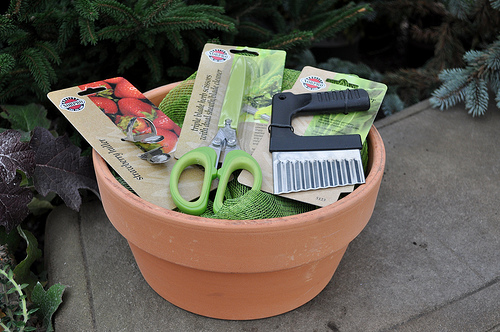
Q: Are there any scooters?
A: No, there are no scooters.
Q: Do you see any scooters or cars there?
A: No, there are no scooters or cars.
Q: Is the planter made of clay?
A: Yes, the planter is made of clay.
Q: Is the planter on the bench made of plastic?
A: No, the planter is made of clay.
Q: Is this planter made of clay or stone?
A: The planter is made of clay.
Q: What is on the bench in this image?
A: The planter is on the bench.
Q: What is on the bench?
A: The planter is on the bench.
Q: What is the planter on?
A: The planter is on the bench.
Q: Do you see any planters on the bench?
A: Yes, there is a planter on the bench.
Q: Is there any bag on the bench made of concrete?
A: No, there is a planter on the bench.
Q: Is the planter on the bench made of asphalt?
A: Yes, the planter is on the bench.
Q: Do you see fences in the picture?
A: No, there are no fences.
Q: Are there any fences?
A: No, there are no fences.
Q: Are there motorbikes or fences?
A: No, there are no fences or motorbikes.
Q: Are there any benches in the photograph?
A: Yes, there is a bench.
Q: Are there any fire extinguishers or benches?
A: Yes, there is a bench.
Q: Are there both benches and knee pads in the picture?
A: No, there is a bench but no knee pads.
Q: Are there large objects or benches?
A: Yes, there is a large bench.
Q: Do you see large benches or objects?
A: Yes, there is a large bench.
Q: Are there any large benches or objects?
A: Yes, there is a large bench.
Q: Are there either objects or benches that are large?
A: Yes, the bench is large.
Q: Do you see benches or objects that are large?
A: Yes, the bench is large.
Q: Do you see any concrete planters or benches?
A: Yes, there is a concrete bench.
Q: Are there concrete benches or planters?
A: Yes, there is a concrete bench.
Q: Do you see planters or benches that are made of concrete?
A: Yes, the bench is made of concrete.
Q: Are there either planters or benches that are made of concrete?
A: Yes, the bench is made of concrete.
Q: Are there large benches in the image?
A: Yes, there is a large bench.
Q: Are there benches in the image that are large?
A: Yes, there is a bench that is large.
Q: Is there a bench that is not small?
A: Yes, there is a large bench.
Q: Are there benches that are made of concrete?
A: Yes, there is a bench that is made of concrete.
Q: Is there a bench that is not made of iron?
A: Yes, there is a bench that is made of concrete.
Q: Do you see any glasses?
A: No, there are no glasses.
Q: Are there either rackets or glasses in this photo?
A: No, there are no glasses or rackets.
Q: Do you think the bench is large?
A: Yes, the bench is large.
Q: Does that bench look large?
A: Yes, the bench is large.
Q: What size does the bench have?
A: The bench has large size.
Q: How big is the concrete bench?
A: The bench is large.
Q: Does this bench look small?
A: No, the bench is large.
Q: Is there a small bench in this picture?
A: No, there is a bench but it is large.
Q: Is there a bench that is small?
A: No, there is a bench but it is large.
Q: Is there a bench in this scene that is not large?
A: No, there is a bench but it is large.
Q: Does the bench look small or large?
A: The bench is large.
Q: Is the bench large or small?
A: The bench is large.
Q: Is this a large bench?
A: Yes, this is a large bench.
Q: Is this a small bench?
A: No, this is a large bench.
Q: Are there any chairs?
A: No, there are no chairs.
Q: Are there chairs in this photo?
A: No, there are no chairs.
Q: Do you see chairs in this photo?
A: No, there are no chairs.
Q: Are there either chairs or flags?
A: No, there are no chairs or flags.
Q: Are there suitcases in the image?
A: No, there are no suitcases.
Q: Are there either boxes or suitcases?
A: No, there are no suitcases or boxes.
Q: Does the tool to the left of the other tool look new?
A: Yes, the tool is new.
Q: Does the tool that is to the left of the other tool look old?
A: No, the tool is new.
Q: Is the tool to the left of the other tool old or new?
A: The tool is new.